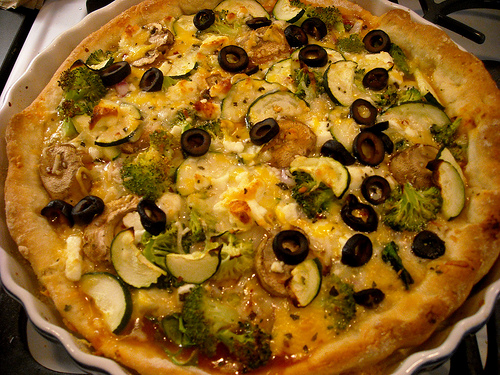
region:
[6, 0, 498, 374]
Round pizza in dish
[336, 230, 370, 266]
Slice of olive on pizza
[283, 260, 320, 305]
Squash on pizza pie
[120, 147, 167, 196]
Broccoli on pizza pie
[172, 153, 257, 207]
Squash covered with cheese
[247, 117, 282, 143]
Slice of olive at an angle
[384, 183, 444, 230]
Flat broccoli floret on cheese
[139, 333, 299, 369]
Red tomato sauce on pizza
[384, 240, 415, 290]
Green vegetable on pizza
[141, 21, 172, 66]
Sliced mushroom on pizza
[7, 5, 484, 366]
a cooked pizza pie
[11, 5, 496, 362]
uncut pie served on a white plate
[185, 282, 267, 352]
broccoli on the pizza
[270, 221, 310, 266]
sliced, black olives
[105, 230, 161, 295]
piece of zucchini on the pie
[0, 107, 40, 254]
cooked crust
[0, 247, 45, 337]
deep dish the pie is set on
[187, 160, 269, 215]
cheese melted on the pizza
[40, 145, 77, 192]
piece of cooked mushroom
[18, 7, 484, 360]
mutli-ingredient pizza with a white sauce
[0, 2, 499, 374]
a white dish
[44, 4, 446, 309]
black olives in halves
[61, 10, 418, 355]
broccoli in dish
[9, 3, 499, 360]
a deep dish casseroll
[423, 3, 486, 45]
utensils on the side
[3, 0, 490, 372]
white trey under dish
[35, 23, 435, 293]
tan mushrooms in pie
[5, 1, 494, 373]
thick crust around pie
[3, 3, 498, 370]
food on the table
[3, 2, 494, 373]
a scene of a dish item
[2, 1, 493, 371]
a white dish pan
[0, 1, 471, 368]
a pizza dish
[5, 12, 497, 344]
a pizza with veggies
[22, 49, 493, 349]
some black olives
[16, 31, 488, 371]
an outer crust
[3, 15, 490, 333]
some green broccoli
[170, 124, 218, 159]
Olives are on the pizza.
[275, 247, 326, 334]
Zuchini is on the pizza.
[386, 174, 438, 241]
Broccoli is on the pizza.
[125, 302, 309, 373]
Sauce is on the pizza.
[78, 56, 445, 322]
Cheese is on the pizza.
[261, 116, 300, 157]
Mushrooms are on the pizza.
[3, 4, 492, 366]
The pizza is in the dish.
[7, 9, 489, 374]
The dish is white.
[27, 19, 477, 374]
The pizza is cooked.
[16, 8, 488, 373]
The dish is white.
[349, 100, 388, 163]
black olives on a pizza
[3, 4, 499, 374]
fully cooked round pizza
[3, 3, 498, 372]
glass white round plate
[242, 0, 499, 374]
right half of the pizza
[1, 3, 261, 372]
left half of the pizza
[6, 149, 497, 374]
bottom half of the pizza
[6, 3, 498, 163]
top half of the pizza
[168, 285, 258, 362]
brocolli on the bottom of the pizza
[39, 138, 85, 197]
mushroom on the left side of the pizza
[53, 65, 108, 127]
brocolli on the left side of the pizza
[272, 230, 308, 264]
slice of black olive on a pizza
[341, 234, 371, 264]
slice of black olive on a pizza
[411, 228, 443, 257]
slice of black olive on a pizza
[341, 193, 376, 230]
slice of black olive on a pizza